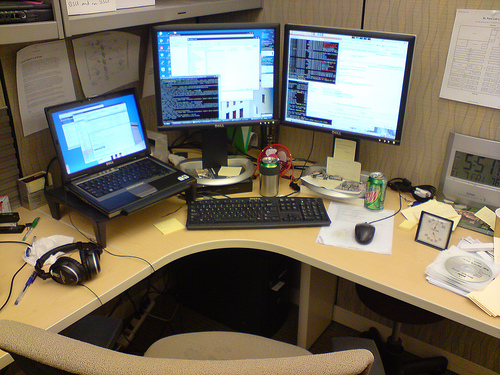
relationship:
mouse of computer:
[354, 221, 374, 245] [146, 21, 416, 230]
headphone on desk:
[33, 240, 102, 287] [1, 149, 498, 368]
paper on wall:
[439, 8, 497, 114] [3, 10, 498, 190]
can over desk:
[364, 171, 389, 211] [1, 149, 498, 368]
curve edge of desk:
[155, 239, 304, 279] [1, 149, 498, 368]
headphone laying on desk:
[34, 241, 103, 286] [1, 149, 498, 368]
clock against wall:
[436, 128, 498, 213] [253, 5, 496, 185]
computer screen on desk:
[285, 30, 409, 140] [1, 149, 498, 368]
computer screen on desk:
[157, 29, 274, 126] [1, 149, 498, 368]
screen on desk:
[42, 82, 146, 176] [1, 149, 498, 368]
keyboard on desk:
[184, 193, 332, 231] [1, 149, 498, 368]